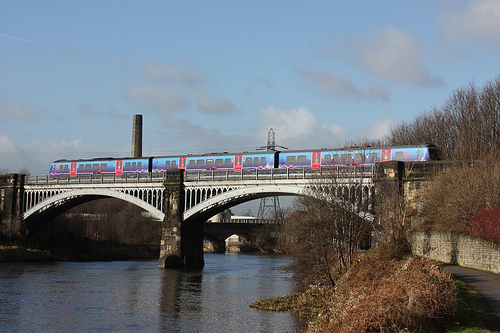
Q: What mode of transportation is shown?
A: Train.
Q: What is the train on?
A: Track.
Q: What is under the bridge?
A: Water.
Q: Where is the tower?
A: Background.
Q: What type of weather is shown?
A: Partly cloudy.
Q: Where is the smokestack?
A: Background.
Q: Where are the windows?
A: Train.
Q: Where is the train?
A: On bridge.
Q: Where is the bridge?
A: Over river.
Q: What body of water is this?
A: River.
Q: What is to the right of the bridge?
A: Hill.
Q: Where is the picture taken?
A: A bridge.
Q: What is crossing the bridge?
A: A train.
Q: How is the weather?
A: Sunny.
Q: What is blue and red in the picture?
A: A train.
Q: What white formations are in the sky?
A: Clouds.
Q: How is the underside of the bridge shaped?
A: Semi-circular.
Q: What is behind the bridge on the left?
A: A smokestack.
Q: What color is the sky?
A: Blue.